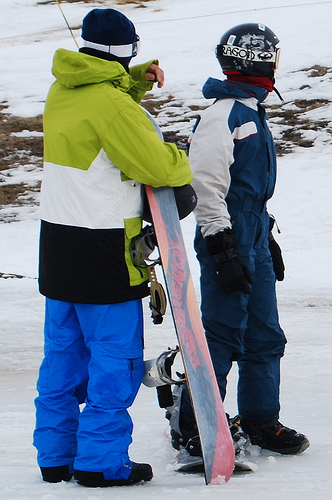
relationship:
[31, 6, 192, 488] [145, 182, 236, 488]
man holding board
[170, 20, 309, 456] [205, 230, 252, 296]
man wearing gloves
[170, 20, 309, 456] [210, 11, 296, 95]
man wearing helmet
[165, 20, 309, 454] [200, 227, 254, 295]
man wearing gloves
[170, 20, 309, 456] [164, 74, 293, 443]
man wearing snow suit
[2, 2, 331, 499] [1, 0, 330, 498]
snow on ground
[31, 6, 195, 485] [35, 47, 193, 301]
man wearing hoodie coat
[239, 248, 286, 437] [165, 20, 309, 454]
leg of a man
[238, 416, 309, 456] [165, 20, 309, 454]
foot of a man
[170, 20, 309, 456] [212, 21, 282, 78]
man wearing helmet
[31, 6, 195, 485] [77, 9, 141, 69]
man wearing beanie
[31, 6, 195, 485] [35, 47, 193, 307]
man wears hoodie coat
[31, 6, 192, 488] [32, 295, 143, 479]
man wears pants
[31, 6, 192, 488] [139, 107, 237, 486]
man holding board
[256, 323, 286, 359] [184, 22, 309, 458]
knee of man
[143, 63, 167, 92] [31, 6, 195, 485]
fingers of man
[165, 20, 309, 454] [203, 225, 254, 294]
man wearing glove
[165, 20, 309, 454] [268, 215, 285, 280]
man wearing glove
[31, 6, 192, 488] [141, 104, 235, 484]
man holding snowboard